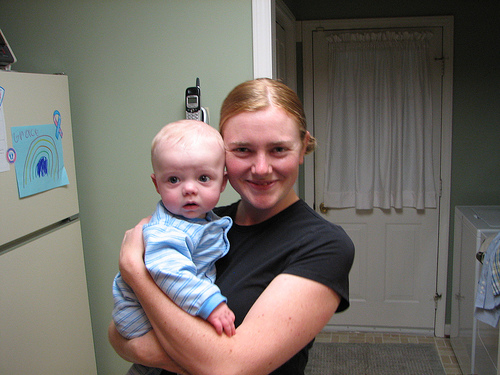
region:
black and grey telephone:
[178, 72, 205, 122]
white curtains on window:
[311, 39, 439, 217]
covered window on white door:
[301, 34, 478, 356]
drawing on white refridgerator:
[6, 110, 94, 210]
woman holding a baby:
[94, 63, 360, 361]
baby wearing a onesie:
[85, 99, 240, 357]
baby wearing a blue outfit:
[114, 111, 251, 356]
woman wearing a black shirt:
[179, 69, 361, 366]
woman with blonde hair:
[205, 65, 334, 176]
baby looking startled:
[141, 118, 231, 277]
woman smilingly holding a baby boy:
[107, 75, 357, 374]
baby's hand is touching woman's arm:
[207, 304, 253, 355]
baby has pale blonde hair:
[146, 118, 222, 168]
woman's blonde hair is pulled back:
[219, 76, 319, 156]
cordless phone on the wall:
[178, 71, 210, 121]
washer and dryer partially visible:
[449, 202, 499, 374]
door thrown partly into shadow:
[304, 16, 451, 336]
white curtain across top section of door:
[318, 30, 440, 215]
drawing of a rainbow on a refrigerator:
[1, 72, 98, 374]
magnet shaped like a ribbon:
[48, 109, 65, 138]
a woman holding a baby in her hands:
[108, 78, 353, 370]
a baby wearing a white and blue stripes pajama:
[111, 198, 231, 339]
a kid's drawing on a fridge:
[8, 123, 70, 196]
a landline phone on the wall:
[184, 76, 207, 123]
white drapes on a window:
[318, 32, 438, 214]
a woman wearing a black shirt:
[213, 196, 352, 372]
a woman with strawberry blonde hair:
[220, 78, 315, 213]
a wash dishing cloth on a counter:
[473, 232, 498, 332]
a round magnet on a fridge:
[5, 147, 18, 164]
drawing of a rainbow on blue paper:
[19, 133, 63, 185]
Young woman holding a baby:
[100, 69, 352, 373]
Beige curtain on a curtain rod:
[316, 29, 441, 210]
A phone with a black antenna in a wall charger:
[181, 75, 206, 122]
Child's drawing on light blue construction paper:
[8, 123, 72, 200]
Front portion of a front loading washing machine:
[449, 204, 499, 374]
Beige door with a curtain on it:
[312, 27, 439, 328]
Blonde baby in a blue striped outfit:
[107, 119, 236, 336]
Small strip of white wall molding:
[250, 0, 275, 74]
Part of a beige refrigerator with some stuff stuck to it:
[0, 69, 100, 373]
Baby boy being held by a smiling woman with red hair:
[99, 66, 356, 373]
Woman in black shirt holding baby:
[108, 65, 354, 374]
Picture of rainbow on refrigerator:
[9, 122, 71, 199]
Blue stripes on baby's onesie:
[111, 204, 232, 338]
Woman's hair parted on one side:
[220, 78, 315, 211]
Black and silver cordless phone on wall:
[179, 75, 209, 120]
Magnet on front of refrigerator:
[50, 110, 65, 137]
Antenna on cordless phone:
[192, 76, 203, 85]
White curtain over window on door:
[313, 28, 444, 212]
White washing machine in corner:
[451, 202, 498, 374]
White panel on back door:
[382, 218, 417, 307]